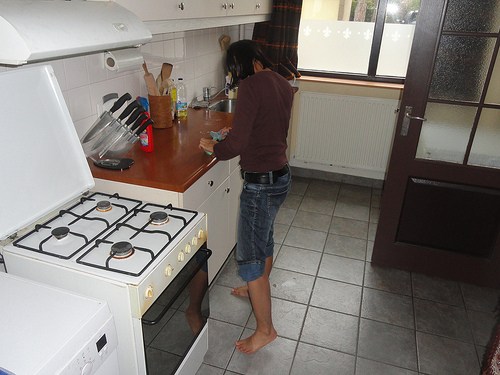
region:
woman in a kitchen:
[0, 0, 489, 373]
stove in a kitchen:
[28, 185, 190, 267]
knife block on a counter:
[82, 86, 163, 175]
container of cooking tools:
[136, 58, 185, 148]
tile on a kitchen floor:
[293, 185, 358, 348]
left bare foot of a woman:
[232, 319, 282, 356]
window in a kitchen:
[296, 1, 402, 79]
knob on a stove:
[133, 280, 158, 307]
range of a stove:
[2, 5, 151, 72]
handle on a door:
[391, 94, 427, 151]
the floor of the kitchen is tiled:
[171, 167, 497, 371]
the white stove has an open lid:
[3, 80, 216, 370]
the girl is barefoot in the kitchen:
[229, 254, 280, 362]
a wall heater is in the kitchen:
[289, 84, 412, 186]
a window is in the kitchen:
[280, 2, 456, 88]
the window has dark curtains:
[256, 0, 479, 80]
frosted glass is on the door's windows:
[415, 5, 499, 218]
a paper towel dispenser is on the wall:
[98, 46, 146, 72]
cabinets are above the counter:
[133, 2, 272, 36]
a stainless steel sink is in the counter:
[187, 80, 257, 120]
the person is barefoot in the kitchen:
[196, 49, 294, 356]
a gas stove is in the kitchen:
[12, 185, 216, 373]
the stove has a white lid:
[0, 68, 109, 262]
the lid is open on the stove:
[1, 66, 207, 284]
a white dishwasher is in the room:
[2, 271, 124, 373]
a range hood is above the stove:
[1, 3, 153, 73]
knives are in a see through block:
[75, 88, 155, 176]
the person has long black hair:
[218, 36, 280, 86]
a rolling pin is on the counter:
[141, 58, 161, 100]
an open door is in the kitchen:
[361, 5, 498, 280]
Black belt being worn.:
[236, 160, 292, 185]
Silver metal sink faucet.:
[191, 80, 231, 100]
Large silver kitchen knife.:
[80, 90, 130, 145]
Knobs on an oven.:
[140, 225, 205, 305]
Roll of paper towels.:
[101, 45, 146, 75]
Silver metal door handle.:
[395, 101, 430, 138]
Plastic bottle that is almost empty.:
[172, 74, 190, 119]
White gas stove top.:
[0, 185, 200, 280]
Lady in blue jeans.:
[195, 35, 290, 355]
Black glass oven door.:
[143, 238, 215, 373]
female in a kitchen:
[211, 38, 283, 350]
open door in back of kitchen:
[378, 4, 498, 289]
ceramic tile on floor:
[209, 183, 474, 363]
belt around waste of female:
[238, 163, 296, 184]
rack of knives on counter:
[86, 93, 155, 177]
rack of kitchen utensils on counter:
[142, 58, 175, 126]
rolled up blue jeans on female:
[233, 171, 293, 280]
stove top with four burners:
[16, 186, 200, 280]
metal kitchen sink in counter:
[201, 83, 238, 116]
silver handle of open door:
[400, 101, 424, 138]